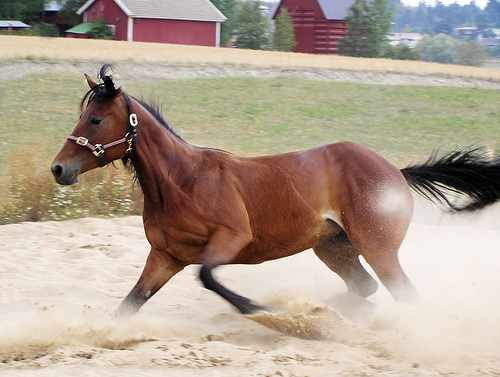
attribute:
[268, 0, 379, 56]
barn — red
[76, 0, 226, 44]
barn — red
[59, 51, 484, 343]
horse — losing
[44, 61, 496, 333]
horse — dirty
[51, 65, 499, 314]
horse — brown, focused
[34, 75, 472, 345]
horse — galloping